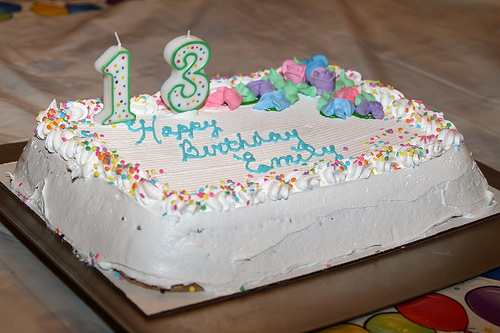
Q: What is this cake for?
A: A birthday.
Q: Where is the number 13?
A: On the cake.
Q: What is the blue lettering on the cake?
A: A written message.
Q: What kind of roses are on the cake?
A: Decorative.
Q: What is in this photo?
A: A cake.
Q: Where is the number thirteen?
A: On the cake.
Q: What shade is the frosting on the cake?
A: Blue.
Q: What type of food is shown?
A: Cake.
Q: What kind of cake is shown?
A: Birthday cake.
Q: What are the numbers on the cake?
A: 13.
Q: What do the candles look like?
A: Numbers.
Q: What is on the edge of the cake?
A: Sprinkles.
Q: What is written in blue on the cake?
A: Happy Birthday Emily.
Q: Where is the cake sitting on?
A: Cardboard.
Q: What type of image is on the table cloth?
A: Balloons.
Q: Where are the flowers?
A: Right side of the numbers.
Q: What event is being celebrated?
A: Birthday.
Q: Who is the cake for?
A: Emily.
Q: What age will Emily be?
A: Thirteen.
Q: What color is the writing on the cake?
A: Blue.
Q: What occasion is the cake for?
A: Birthday.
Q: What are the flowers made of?
A: Icing.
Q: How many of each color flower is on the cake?
A: Three.